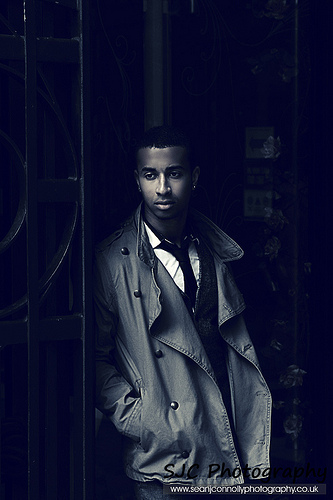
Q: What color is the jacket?
A: Gray.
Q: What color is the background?
A: Black.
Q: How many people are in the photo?
A: One.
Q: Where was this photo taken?
A: By the black door.